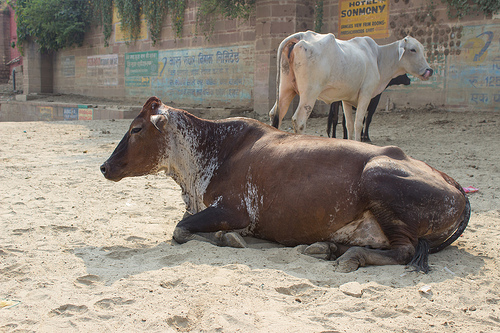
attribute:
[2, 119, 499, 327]
ground — sandy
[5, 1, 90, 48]
shrub — green, hanging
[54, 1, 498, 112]
wall — brown, stone, grey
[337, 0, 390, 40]
sign — yellow, painted, faded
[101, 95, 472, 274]
cow — brown, resting, browny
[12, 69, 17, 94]
post — metal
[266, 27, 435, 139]
heifer — standing, white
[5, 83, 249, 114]
walkway — sandy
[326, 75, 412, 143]
calf — black, white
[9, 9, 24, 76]
door — red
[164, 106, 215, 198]
neck — white